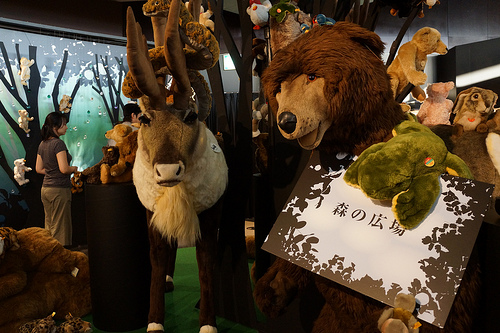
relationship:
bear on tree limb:
[384, 25, 452, 112] [0, 99, 35, 137]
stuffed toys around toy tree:
[99, 0, 497, 332] [197, 0, 423, 328]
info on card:
[326, 195, 406, 237] [258, 130, 490, 329]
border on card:
[449, 227, 484, 287] [258, 130, 490, 329]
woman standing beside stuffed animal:
[32, 110, 80, 247] [59, 95, 74, 116]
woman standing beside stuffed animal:
[32, 110, 80, 247] [21, 55, 36, 92]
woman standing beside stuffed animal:
[32, 110, 80, 247] [18, 109, 39, 140]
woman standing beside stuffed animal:
[32, 110, 80, 247] [13, 155, 32, 188]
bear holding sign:
[384, 25, 452, 112] [258, 152, 495, 329]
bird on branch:
[244, 0, 271, 29] [0, 100, 34, 135]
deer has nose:
[83, 15, 307, 264] [152, 157, 182, 187]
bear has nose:
[384, 25, 452, 112] [351, 158, 411, 205]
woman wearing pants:
[32, 110, 80, 254] [40, 186, 74, 248]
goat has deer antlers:
[101, 17, 238, 255] [123, 4, 168, 108]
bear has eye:
[384, 25, 452, 112] [295, 72, 323, 87]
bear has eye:
[258, 23, 413, 331] [271, 83, 281, 95]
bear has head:
[384, 25, 452, 112] [262, 19, 392, 151]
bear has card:
[236, 30, 460, 330] [263, 140, 482, 315]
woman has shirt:
[32, 110, 80, 254] [37, 135, 80, 189]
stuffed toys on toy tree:
[342, 118, 477, 232] [197, 0, 431, 331]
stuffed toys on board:
[342, 118, 477, 232] [257, 137, 495, 328]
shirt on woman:
[35, 135, 78, 188] [22, 108, 76, 240]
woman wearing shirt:
[32, 110, 80, 247] [37, 135, 80, 189]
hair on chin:
[147, 177, 204, 249] [156, 182, 183, 188]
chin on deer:
[156, 182, 183, 188] [121, 0, 231, 332]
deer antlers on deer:
[117, 7, 211, 108] [110, 23, 204, 222]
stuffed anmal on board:
[342, 115, 452, 225] [257, 137, 494, 328]